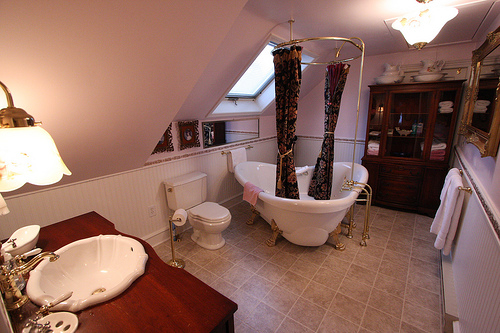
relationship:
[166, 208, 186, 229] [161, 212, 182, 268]
paper on dispenser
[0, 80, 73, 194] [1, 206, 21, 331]
lamp on table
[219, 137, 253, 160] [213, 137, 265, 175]
holder on wall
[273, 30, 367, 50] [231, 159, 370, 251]
ring over bathtub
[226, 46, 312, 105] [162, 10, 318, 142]
light in roof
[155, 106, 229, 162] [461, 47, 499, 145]
pictures beside mirror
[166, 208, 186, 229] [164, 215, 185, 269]
paper on holder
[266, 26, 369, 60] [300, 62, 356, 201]
tassel holds curtain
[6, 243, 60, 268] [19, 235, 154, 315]
faucet above sink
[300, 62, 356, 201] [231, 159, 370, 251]
curtain in bathtub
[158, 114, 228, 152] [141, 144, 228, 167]
frames on ledge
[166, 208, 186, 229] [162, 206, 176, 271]
paper on stand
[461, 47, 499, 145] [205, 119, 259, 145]
mirror under window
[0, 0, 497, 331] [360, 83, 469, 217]
bathroom under hutch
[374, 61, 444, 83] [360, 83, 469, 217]
basins on top of hutch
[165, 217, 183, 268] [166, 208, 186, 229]
stand of paper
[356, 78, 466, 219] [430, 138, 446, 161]
cabinet for towels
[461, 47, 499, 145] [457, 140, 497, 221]
mirror on wall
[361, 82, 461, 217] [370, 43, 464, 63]
cabinet against wall